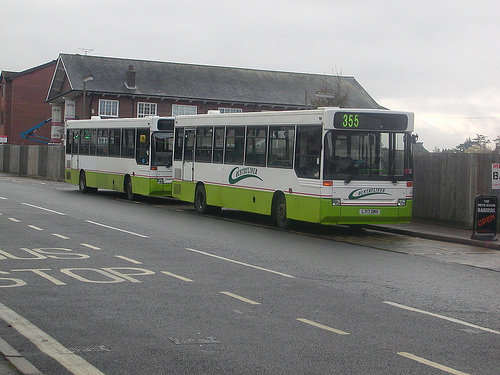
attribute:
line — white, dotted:
[20, 200, 66, 218]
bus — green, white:
[170, 106, 415, 231]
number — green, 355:
[341, 113, 360, 129]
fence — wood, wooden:
[334, 151, 499, 234]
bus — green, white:
[64, 114, 173, 202]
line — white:
[84, 218, 148, 240]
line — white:
[184, 246, 296, 283]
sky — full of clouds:
[1, 2, 500, 153]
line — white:
[116, 254, 144, 266]